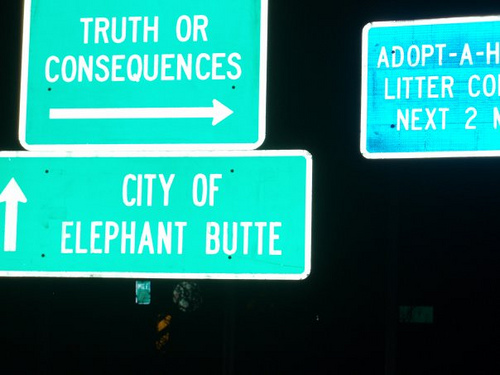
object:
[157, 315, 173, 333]
pole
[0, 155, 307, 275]
green sign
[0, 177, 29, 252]
arrow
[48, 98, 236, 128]
arrow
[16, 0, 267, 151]
sign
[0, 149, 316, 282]
directional sign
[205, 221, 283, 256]
butte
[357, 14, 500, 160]
sign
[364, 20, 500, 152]
board color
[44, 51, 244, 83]
word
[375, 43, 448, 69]
word adopt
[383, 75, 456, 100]
litter